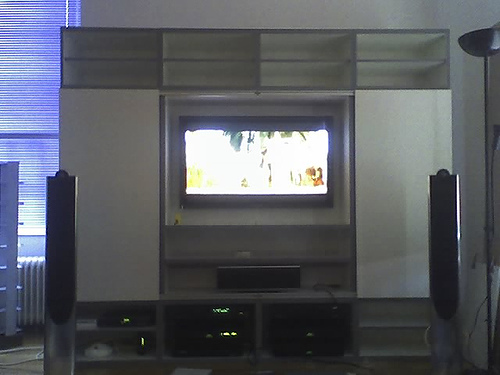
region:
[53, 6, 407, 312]
a television in a home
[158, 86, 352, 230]
this TV is built into the wall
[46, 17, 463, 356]
this is a large entertainment center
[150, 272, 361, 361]
these are components for the entertainment center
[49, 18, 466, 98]
this is the top of the entertainment center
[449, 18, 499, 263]
the lamp pole in the room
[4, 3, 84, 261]
shades on the wall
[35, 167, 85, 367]
speakers on the wall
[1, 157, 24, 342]
an object in the living room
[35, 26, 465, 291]
this is a huge entertainment area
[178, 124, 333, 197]
a television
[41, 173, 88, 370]
speakers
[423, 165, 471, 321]
a tall speaker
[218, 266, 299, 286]
a small speaker below the television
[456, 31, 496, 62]
a black lamp shade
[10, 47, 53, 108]
blinds on the window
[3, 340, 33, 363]
white cord on the floor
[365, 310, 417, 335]
a white shelf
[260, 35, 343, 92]
white shelves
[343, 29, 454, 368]
a black lamp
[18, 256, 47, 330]
Radiator on the wall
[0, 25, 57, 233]
Venetian blinds covering window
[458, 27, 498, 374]
Pole lamp in corner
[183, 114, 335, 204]
Television screen turned on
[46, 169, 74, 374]
Speakers for sound system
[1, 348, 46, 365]
Power cords for electronics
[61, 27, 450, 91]
Shelf space on entertainment center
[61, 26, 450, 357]
Entertainment system for electronics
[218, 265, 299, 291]
DVD player for television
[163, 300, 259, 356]
Stereo for sound system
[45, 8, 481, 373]
A large entertainment center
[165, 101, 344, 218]
A flat screen television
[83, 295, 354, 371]
electronic equipment for a media center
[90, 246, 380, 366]
Media center equipment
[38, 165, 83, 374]
A large speaker for a television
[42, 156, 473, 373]
Two large speakers for a media center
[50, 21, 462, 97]
Shelves above a television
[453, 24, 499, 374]
A tall black lamp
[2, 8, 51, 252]
A large window with blinds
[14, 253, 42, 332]
A radiator near a wall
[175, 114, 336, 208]
a rectangular television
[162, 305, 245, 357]
a stack of black electronic boxes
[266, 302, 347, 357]
entertainment devices with lights on the front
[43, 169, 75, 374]
a tall, skinny speaker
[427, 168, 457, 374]
a black and grey speaker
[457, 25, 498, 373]
a tall black floor lamp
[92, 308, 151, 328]
a black DVD player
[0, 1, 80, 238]
a window with a shade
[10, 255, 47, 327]
a white radiator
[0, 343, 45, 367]
a white electrical cord